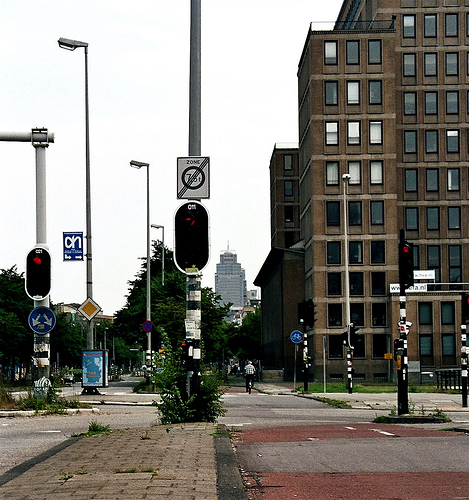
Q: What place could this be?
A: It is a road.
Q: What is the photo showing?
A: It is showing a road.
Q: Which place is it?
A: It is a road.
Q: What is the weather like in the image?
A: It is cloudy.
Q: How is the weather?
A: It is cloudy.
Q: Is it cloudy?
A: Yes, it is cloudy.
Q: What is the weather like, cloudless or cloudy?
A: It is cloudy.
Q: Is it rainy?
A: No, it is cloudy.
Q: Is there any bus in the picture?
A: No, there are no buses.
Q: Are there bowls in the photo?
A: No, there are no bowls.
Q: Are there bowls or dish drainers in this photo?
A: No, there are no bowls or dish drainers.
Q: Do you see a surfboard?
A: No, there are no surfboards.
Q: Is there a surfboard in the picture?
A: No, there are no surfboards.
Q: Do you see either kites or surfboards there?
A: No, there are no surfboards or kites.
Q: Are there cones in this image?
A: No, there are no cones.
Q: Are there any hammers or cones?
A: No, there are no cones or hammers.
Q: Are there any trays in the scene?
A: No, there are no trays.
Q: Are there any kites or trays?
A: No, there are no trays or kites.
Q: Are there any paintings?
A: No, there are no paintings.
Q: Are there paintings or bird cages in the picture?
A: No, there are no paintings or bird cages.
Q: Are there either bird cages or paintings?
A: No, there are no paintings or bird cages.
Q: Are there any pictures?
A: No, there are no pictures.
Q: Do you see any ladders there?
A: No, there are no ladders.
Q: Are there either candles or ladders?
A: No, there are no ladders or candles.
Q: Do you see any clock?
A: No, there are no clocks.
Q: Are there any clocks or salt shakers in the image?
A: No, there are no clocks or salt shakers.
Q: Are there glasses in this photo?
A: No, there are no glasses.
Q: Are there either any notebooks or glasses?
A: No, there are no glasses or notebooks.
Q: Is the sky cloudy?
A: Yes, the sky is cloudy.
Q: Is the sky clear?
A: No, the sky is cloudy.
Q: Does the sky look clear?
A: No, the sky is cloudy.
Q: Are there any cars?
A: No, there are no cars.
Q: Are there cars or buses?
A: No, there are no cars or buses.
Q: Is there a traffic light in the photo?
A: Yes, there is a traffic light.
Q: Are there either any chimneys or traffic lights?
A: Yes, there is a traffic light.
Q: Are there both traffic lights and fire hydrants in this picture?
A: No, there is a traffic light but no fire hydrants.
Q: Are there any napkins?
A: No, there are no napkins.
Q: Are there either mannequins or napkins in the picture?
A: No, there are no napkins or mannequins.